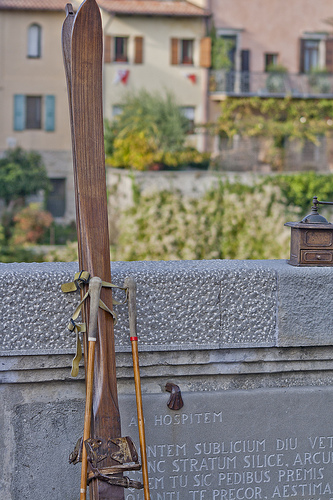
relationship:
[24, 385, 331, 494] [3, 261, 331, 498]
letter on slab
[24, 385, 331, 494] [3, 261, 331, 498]
letter on top of slab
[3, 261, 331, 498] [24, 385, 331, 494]
slab has letter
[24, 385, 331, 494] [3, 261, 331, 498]
letter on side of slab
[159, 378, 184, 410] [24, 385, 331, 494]
bracket holding letter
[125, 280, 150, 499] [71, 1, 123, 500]
handle for ski poles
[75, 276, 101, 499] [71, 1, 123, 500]
handle for ski poles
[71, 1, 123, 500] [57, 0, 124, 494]
ski poles are tied together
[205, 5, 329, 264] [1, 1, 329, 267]
builduing in background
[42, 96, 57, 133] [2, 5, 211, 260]
shutter on builduing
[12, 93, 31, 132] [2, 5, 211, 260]
shutter on builduing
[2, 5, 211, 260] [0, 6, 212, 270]
builduing on left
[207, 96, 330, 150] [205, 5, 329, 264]
plant around builduing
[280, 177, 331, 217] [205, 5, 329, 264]
plant around builduing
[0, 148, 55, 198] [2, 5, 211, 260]
plant around builduing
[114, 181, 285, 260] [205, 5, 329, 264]
shrubbery around builduing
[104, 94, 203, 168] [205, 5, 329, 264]
shrubbery around builduing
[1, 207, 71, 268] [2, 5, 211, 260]
shrubbery around builduing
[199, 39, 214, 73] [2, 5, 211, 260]
shutter on builduing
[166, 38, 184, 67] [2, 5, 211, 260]
shutter on builduing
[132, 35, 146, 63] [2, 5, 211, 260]
shutter on builduing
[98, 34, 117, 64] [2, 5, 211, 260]
shutter on builduing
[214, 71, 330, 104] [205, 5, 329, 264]
balcony on builduing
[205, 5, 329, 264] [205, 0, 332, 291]
builduing on right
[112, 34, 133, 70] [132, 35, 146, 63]
window has shutter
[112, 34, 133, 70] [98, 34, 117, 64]
window has shutter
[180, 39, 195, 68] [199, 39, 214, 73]
window has shutter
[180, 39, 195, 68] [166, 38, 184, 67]
window has shutter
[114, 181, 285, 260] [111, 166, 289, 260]
shrubbery growing on wall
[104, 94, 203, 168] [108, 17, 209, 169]
shrubbery growing on wall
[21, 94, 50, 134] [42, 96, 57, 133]
window has shutter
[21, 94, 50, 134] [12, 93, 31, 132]
window has shutter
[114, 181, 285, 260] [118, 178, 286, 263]
shrubbery has leaves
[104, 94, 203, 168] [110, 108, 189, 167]
shrubbery has leaves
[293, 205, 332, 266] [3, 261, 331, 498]
grinder on top of slab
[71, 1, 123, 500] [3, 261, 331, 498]
ski poles are leaning to slab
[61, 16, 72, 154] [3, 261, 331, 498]
ski poles are leaning to slab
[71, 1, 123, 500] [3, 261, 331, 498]
ski poles are leaning against slab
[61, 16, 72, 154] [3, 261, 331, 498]
ski poles are leaning against slab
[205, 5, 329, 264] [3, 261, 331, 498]
builduing behind slab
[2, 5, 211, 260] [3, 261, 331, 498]
builduing behind slab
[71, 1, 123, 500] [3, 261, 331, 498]
ski poles are on slab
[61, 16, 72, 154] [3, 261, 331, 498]
ski poles are on slab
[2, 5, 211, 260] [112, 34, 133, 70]
builduing has window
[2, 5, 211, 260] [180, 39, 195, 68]
builduing has window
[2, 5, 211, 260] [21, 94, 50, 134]
builduing has window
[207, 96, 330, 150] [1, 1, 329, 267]
plant in background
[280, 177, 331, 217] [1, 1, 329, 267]
plant in background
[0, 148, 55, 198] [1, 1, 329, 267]
plant in background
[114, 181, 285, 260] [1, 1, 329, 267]
shrubbery in background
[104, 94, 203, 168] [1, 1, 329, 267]
shrubbery in background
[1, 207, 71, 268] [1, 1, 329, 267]
shrubbery in background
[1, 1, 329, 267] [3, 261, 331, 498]
background behind slab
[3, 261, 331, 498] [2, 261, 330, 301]
slab has top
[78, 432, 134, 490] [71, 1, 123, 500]
straps on ski poles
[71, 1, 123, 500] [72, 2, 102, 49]
ski poles has top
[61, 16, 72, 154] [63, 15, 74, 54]
ski poles has top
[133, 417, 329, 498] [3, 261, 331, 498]
ingrave on slab